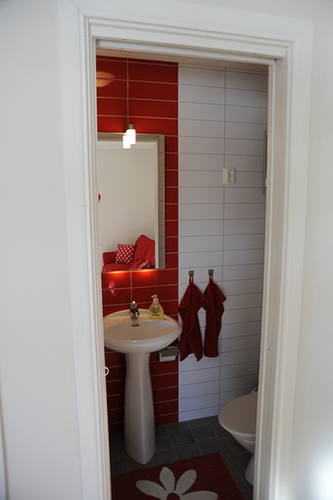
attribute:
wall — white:
[180, 66, 268, 281]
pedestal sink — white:
[100, 300, 183, 465]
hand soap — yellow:
[148, 295, 167, 322]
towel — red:
[201, 273, 226, 357]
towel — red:
[178, 280, 208, 361]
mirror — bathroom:
[93, 135, 171, 272]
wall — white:
[97, 71, 261, 121]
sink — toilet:
[103, 307, 181, 464]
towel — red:
[176, 278, 204, 360]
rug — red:
[112, 451, 243, 499]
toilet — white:
[216, 385, 257, 484]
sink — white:
[100, 297, 187, 468]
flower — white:
[133, 462, 219, 497]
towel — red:
[198, 269, 227, 358]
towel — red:
[176, 275, 207, 364]